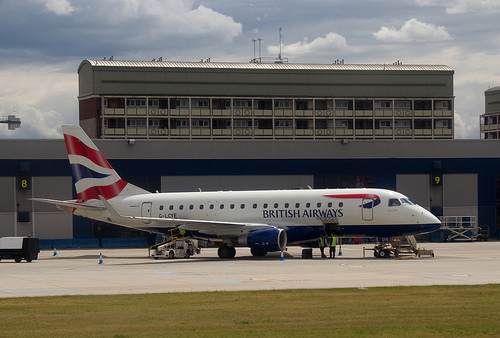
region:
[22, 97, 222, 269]
Red, white and blue logo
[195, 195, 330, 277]
Jet engine under wing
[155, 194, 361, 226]
18 passenger windows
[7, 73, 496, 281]
Plane between gate 8 and 9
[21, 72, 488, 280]
British Airways jet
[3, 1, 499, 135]
Plenty of clouds in the sky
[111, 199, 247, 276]
Baggage door open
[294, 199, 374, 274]
Two men wearing green vests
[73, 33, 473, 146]
Where the airport employees work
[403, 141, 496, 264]
Number nine above the lift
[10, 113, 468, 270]
Commercial airliner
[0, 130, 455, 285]
White, blue and red airplane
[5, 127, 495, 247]
Airplane hangers in the background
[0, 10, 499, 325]
An airplane at an airport on the tarmac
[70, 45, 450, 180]
A building at the airport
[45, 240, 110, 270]
Two blue cones on tarmac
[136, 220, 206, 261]
Mobile conveyer belt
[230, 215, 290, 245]
A blue jet engine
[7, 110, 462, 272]
Jet powered airplane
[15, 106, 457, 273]
British Airways commercial jet airplane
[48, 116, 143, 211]
the tail of the airplane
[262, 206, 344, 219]
the blue lettering on the plane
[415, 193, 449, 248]
the nose of the airplane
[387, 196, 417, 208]
the windshield of the cockpit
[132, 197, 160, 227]
the rear door of the aircraft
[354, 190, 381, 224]
the forward door of the aircraft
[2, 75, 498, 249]
the terminal building behind the aircraft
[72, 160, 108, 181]
the blue stripe on the tail of the airplane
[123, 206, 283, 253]
the wing of the airplane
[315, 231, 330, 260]
the worker leaning on the aircraft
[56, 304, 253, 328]
well manicured green grass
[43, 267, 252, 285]
long tan airport tarmac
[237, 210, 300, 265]
blue and silver wing on plane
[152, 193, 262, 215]
small windows in the airplane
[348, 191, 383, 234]
large closed door on the plane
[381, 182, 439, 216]
windows in the front of the plane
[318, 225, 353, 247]
man wearing bright yellow vest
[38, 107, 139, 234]
blue and red marking on plane's wing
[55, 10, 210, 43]
blue and white clouds in the sky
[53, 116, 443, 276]
large passenger plane on the tarmac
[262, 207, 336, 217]
Name of airplane carrier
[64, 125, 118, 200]
red, white and blue tail of airplane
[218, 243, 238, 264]
a wheel on the airplane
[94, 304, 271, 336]
grassy area near runway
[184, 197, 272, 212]
passenger windows on airplane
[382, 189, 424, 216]
cockpit area of airplane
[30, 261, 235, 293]
part of the airplane runway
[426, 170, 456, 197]
gate number at airport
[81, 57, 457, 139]
airport terminal in back of airplane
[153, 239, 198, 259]
white truck near airplane